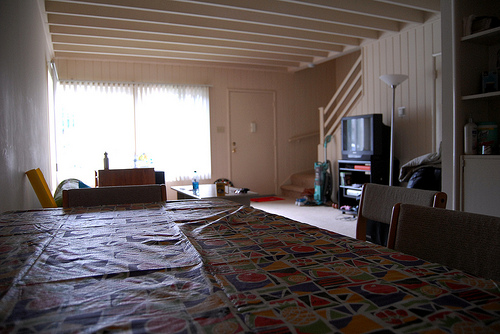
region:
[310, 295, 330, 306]
pattern on the tablecloth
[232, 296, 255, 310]
pattern on the tablecloth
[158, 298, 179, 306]
pattern on the tablecloth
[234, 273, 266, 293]
pattern on the tablecloth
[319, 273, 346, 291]
pattern on the tablecloth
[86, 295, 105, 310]
pattern on the tablecloth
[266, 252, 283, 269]
pattern on the tablecloth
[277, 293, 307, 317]
pattern on the tablecloth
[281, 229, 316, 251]
pattern on the tablecloth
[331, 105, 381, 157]
tv on the stand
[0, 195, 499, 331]
Colorful all over print table cloth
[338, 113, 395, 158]
Old school big screen tv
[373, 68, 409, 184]
White and silver lamp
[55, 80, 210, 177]
Bright light coming through window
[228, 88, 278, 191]
Cream white door matching wall color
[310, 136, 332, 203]
Baby blue vacuum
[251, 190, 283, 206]
Red floor mat in front of door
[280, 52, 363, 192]
Stairs leading to the upper level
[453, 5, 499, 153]
Shelves with items on it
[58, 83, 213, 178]
White blinds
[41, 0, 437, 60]
light colored ceiling beams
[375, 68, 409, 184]
one gray and white floor lamp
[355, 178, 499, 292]
two wooden chairs at table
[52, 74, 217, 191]
large sunlit rectangular window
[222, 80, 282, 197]
one light colored rectangular door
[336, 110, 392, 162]
one dark large TV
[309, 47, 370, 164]
light colored wooden stair banister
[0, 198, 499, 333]
one multicolored plastic tablecloth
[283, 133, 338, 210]
one vacuum cleaner at base of stairs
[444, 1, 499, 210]
light colored wooden shelving in shadow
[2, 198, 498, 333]
a festive tablecloth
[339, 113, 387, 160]
a TV on a black stand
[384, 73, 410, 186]
a stand up lamp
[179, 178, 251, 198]
a coffee table with items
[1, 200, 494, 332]
a tablecloth with colored shape pattern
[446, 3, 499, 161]
a white shelf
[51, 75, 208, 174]
a large covered window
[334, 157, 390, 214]
a black entertainment stand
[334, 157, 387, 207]
a small tv stand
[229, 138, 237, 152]
gold installations on door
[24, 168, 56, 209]
A large yellow thing up against a wall.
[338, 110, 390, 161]
A black television that isn't on.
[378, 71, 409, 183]
A tall white lamp with a long silver pole.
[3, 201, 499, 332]
A colorful plastic table cloth.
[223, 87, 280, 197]
A tan door.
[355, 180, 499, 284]
Two grey and brown chairs to the right of a table.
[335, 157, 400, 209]
Dark colored stand a tv is on.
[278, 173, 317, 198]
Two tan steps by a door.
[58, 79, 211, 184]
Two very large windows in a room.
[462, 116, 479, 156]
A large white bottle of lotion on a shelf to the right of a tv.